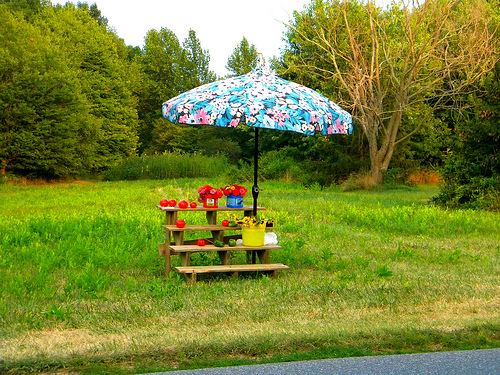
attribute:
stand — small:
[143, 181, 295, 297]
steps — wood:
[158, 185, 291, 281]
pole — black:
[251, 125, 264, 213]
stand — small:
[160, 195, 275, 286]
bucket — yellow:
[230, 213, 275, 248]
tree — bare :
[323, 36, 473, 156]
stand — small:
[135, 187, 294, 308]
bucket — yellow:
[239, 222, 266, 252]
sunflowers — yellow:
[230, 215, 268, 230]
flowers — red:
[193, 171, 255, 213]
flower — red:
[240, 187, 247, 193]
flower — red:
[233, 188, 238, 195]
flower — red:
[224, 188, 231, 195]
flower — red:
[230, 184, 237, 189]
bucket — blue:
[227, 194, 245, 209]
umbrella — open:
[150, 50, 380, 149]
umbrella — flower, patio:
[164, 50, 366, 204]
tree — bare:
[300, 2, 497, 207]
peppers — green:
[201, 160, 331, 297]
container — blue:
[224, 191, 244, 208]